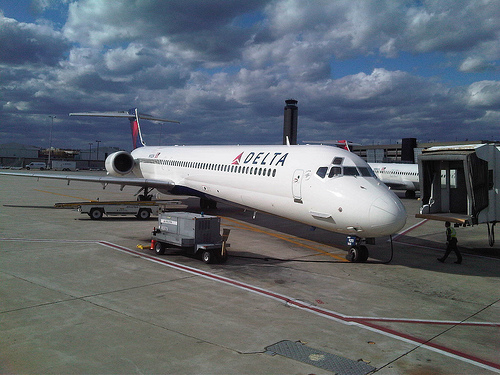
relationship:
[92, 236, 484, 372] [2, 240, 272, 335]
line on tarmac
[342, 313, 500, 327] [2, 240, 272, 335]
lines on tarmac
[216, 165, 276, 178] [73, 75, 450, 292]
windows on a plane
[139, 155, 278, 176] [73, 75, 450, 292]
row on a plane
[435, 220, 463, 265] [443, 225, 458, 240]
man wearing a safety vest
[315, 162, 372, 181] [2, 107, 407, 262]
cockpit on plane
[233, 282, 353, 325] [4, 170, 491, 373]
lines on tarmac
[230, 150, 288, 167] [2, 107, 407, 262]
delta logo on plane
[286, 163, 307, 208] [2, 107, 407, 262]
exit on plane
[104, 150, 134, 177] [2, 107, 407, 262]
engine on plane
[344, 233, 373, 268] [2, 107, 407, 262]
wheel of plane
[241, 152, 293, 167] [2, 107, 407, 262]
letters on plane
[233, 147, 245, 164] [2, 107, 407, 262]
insignia on plane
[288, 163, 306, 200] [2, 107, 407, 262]
door on plane